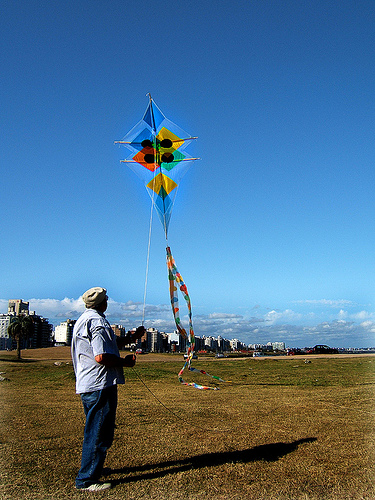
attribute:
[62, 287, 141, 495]
man — standing, flying, wearing, elderly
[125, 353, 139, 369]
hand — holding, man's, flying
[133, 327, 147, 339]
hand — holding, flying, man's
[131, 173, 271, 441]
string — attached, kite's, white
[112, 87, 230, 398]
kite — multi colored, flying, blue, orange, yellow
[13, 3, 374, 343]
sky — clear, blue, daytime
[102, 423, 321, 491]
shadow — man's, cast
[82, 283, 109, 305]
cap — gray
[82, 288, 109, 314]
head — man's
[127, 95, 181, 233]
design — colored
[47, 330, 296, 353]
line — buildings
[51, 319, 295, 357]
buildings — city, lining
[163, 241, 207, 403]
tail — multi colored, kite's, colorful, polka dot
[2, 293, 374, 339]
clouds — low, gray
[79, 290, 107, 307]
hat — gray, man's, colored, light, white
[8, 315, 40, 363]
palm tree — lone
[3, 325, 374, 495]
field — large, open, grassy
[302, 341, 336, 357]
truck — pickup, black, parked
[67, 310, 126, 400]
shirt — blue, short sleeved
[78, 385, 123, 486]
jeans — blue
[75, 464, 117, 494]
sneakers — white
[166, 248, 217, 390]
dots — colorful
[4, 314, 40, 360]
tree — tall, green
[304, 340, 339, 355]
car — black, small, parked